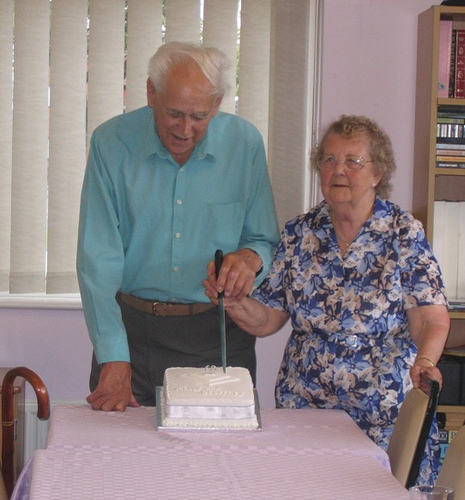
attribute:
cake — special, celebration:
[160, 362, 258, 428]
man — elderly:
[62, 33, 283, 415]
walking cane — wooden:
[3, 361, 51, 497]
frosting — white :
[198, 381, 203, 382]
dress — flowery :
[253, 198, 449, 419]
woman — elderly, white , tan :
[220, 115, 451, 492]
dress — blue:
[251, 202, 452, 497]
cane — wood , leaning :
[6, 366, 46, 484]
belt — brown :
[116, 291, 220, 316]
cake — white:
[153, 367, 261, 436]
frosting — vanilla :
[198, 386, 211, 399]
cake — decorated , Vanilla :
[154, 362, 262, 429]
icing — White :
[224, 394, 234, 402]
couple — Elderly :
[75, 43, 447, 487]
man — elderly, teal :
[73, 41, 279, 409]